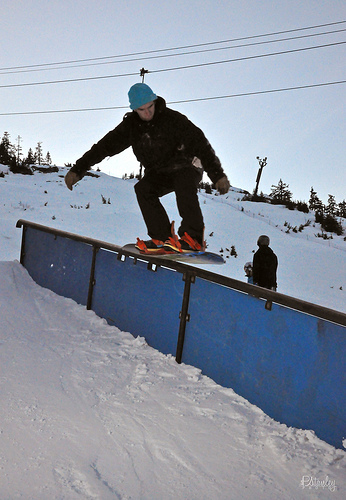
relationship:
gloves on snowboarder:
[213, 179, 233, 190] [82, 85, 224, 252]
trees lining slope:
[251, 178, 329, 223] [234, 205, 288, 234]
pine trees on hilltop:
[1, 127, 56, 174] [4, 152, 192, 264]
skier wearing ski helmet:
[248, 232, 278, 294] [258, 233, 270, 248]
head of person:
[129, 81, 157, 122] [45, 75, 228, 248]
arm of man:
[174, 109, 228, 181] [64, 80, 232, 251]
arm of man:
[72, 125, 126, 179] [64, 80, 232, 251]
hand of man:
[212, 177, 232, 193] [64, 80, 232, 251]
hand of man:
[61, 162, 83, 190] [64, 80, 232, 251]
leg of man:
[128, 169, 175, 238] [64, 80, 232, 251]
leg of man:
[176, 173, 206, 241] [64, 80, 232, 251]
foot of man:
[133, 228, 177, 250] [64, 80, 232, 251]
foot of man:
[172, 235, 209, 253] [64, 80, 232, 251]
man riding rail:
[64, 80, 232, 251] [17, 217, 344, 325]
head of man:
[129, 81, 157, 119] [50, 80, 235, 251]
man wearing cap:
[50, 80, 235, 251] [125, 81, 158, 106]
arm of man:
[174, 109, 228, 181] [50, 80, 235, 251]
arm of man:
[72, 113, 133, 179] [50, 80, 235, 251]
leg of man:
[176, 173, 206, 241] [50, 80, 235, 251]